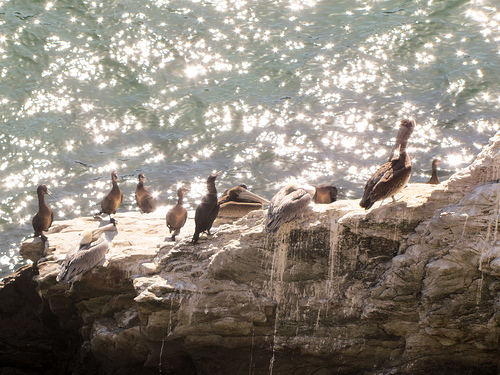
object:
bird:
[31, 185, 56, 239]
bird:
[17, 231, 56, 274]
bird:
[53, 217, 120, 286]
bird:
[96, 171, 122, 219]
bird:
[132, 172, 159, 215]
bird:
[161, 185, 194, 242]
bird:
[358, 114, 411, 212]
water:
[0, 0, 499, 281]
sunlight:
[77, 102, 92, 114]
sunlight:
[179, 65, 204, 82]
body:
[360, 149, 414, 204]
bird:
[187, 172, 225, 244]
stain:
[281, 227, 331, 283]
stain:
[350, 235, 404, 262]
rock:
[0, 129, 500, 375]